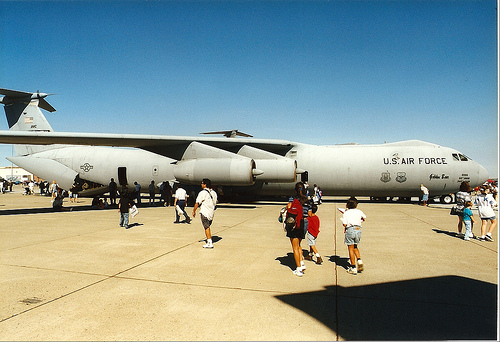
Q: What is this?
A: A plane.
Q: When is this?
A: Daytime.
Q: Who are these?
A: People.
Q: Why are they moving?
A: To enter the plane.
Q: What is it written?
A: Us air force.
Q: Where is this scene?
A: At an airport.